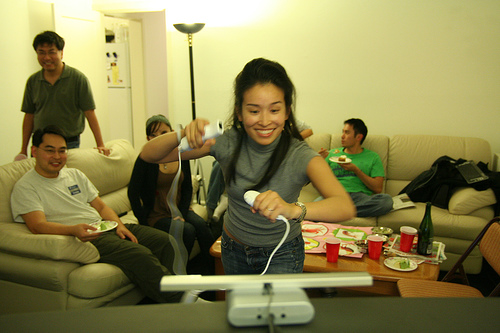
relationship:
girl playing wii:
[210, 57, 355, 316] [158, 116, 381, 291]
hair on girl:
[230, 49, 295, 168] [215, 51, 311, 271]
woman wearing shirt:
[211, 58, 321, 243] [210, 133, 311, 250]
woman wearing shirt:
[211, 58, 321, 243] [216, 135, 303, 250]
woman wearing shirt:
[211, 58, 321, 243] [213, 132, 315, 255]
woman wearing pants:
[211, 58, 321, 243] [213, 230, 303, 270]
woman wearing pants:
[211, 58, 321, 243] [219, 234, 306, 271]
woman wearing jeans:
[211, 58, 321, 243] [210, 233, 305, 274]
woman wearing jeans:
[211, 58, 321, 243] [215, 223, 305, 274]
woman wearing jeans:
[211, 58, 321, 243] [225, 218, 318, 288]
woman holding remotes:
[220, 83, 312, 230] [155, 109, 300, 231]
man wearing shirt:
[324, 115, 394, 220] [340, 150, 373, 188]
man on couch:
[321, 101, 398, 217] [354, 68, 454, 246]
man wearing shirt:
[27, 164, 124, 246] [21, 172, 111, 232]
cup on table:
[304, 220, 344, 271] [356, 246, 379, 281]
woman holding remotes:
[211, 58, 321, 243] [157, 104, 275, 230]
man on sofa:
[38, 143, 127, 287] [80, 152, 115, 193]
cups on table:
[290, 204, 410, 286] [382, 261, 452, 309]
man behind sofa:
[17, 24, 97, 145] [89, 143, 119, 190]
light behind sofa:
[171, 19, 210, 113] [384, 123, 448, 179]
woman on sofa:
[138, 113, 190, 223] [395, 136, 445, 169]